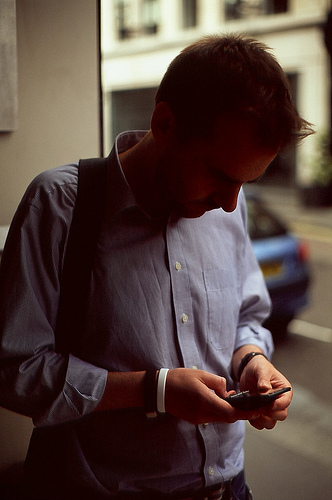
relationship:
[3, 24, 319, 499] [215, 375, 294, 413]
man holding phone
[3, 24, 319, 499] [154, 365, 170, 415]
man has bracelet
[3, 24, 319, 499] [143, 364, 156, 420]
man has bracelet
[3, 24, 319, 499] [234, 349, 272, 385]
man wearing watch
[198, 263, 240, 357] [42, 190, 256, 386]
pocket on shirt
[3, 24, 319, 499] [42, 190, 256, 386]
man has shirt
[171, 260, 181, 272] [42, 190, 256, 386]
button on shirt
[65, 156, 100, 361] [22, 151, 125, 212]
strap over shoulder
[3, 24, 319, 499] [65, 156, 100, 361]
man has strap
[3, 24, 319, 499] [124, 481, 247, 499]
man wearing belt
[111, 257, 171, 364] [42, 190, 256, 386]
wrinkles on shirt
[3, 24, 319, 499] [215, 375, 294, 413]
man with phone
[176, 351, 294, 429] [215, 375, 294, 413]
hands holding phone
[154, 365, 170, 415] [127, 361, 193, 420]
band on wrist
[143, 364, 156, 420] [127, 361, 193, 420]
band on wrist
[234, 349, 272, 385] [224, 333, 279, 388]
watch on wrist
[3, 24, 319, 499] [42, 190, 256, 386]
man wearing shirt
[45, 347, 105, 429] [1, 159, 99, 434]
rolled up sleeve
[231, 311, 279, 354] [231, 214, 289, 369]
rolled up sleeve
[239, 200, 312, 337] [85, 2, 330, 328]
car outside window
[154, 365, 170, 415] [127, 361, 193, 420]
bracelet on wrist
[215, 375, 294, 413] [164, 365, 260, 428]
cell in hands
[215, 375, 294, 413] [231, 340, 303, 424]
cell in hand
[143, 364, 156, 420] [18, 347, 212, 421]
bracelet on arm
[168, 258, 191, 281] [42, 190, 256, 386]
button on shirt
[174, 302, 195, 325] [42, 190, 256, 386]
button on shirt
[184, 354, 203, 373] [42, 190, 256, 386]
button on shirt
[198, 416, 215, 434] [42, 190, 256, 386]
button on shirt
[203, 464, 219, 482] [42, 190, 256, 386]
button on shirt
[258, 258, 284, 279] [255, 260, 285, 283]
plate license plate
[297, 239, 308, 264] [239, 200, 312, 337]
red of car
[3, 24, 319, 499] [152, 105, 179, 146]
man's right ear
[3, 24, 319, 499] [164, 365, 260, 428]
man's right hands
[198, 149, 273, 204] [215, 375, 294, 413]
looking at phone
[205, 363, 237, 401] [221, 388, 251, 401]
thumb pushing button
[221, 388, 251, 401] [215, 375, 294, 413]
button on phone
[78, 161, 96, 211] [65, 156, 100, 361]
black should strap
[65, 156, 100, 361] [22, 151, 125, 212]
strap on shoulder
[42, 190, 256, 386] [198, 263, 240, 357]
shirt breast pocket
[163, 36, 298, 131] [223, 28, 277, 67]
hair sticking up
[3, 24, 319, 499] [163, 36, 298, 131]
man has hair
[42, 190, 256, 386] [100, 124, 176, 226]
shirt has collar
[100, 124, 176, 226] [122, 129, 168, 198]
collar around neck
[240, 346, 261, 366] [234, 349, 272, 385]
buckle on band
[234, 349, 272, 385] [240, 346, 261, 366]
band and buckle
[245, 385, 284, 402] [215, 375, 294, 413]
screen on cell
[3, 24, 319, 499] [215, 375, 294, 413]
man using cell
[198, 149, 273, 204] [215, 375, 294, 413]
looking at cell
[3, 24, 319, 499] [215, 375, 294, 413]
man checking phone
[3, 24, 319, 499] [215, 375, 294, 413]
person using phone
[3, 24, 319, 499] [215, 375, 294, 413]
person holding phone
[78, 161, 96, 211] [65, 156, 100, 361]
dark shoulder strap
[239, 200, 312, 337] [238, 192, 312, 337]
rear end of car